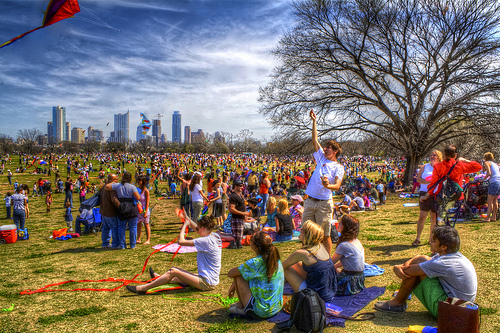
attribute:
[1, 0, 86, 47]
kite — red, flying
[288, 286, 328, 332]
backpack — black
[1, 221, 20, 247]
cooler —  orange,  white, red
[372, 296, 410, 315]
shoes — grey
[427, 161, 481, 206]
shirt — red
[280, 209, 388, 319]
people — sitting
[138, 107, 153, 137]
kite — blue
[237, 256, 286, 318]
shirt — green, blue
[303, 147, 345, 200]
shirt — white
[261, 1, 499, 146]
tree —  leafless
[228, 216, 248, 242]
shorts — plaid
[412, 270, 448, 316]
shorts — green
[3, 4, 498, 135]
sky — cloudy, blue, clear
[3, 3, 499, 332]
scene — painting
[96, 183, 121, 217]
around each other — brown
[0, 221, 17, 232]
lid — white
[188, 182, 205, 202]
shirt — white